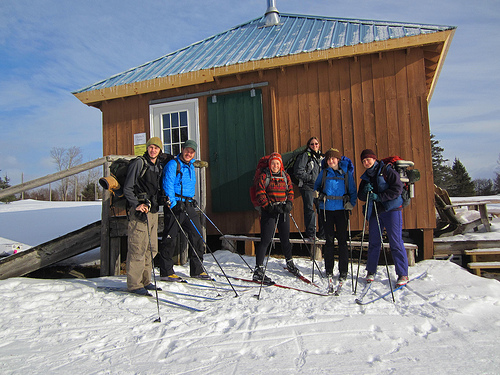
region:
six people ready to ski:
[60, 5, 477, 342]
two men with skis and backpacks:
[92, 124, 234, 311]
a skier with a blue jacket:
[158, 135, 239, 297]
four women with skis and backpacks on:
[247, 132, 442, 317]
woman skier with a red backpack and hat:
[246, 147, 310, 296]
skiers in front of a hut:
[57, 2, 499, 337]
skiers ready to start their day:
[53, 5, 480, 364]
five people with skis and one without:
[55, 24, 485, 361]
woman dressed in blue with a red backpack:
[356, 143, 435, 307]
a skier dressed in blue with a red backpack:
[352, 144, 449, 326]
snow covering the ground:
[192, 323, 390, 372]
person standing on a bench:
[288, 129, 322, 244]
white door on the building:
[138, 98, 195, 141]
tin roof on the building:
[134, 20, 355, 58]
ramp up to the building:
[5, 159, 106, 269]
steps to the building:
[453, 244, 499, 295]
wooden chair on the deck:
[433, 180, 498, 252]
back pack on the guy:
[91, 148, 133, 202]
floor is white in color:
[271, 321, 316, 371]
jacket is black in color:
[146, 159, 164, 194]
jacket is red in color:
[263, 175, 291, 208]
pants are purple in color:
[389, 215, 411, 267]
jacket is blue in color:
[321, 167, 358, 205]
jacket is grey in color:
[295, 148, 313, 178]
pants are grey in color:
[126, 213, 160, 285]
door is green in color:
[211, 108, 255, 158]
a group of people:
[109, 125, 431, 309]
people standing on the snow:
[97, 123, 424, 310]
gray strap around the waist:
[323, 189, 347, 201]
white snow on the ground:
[2, 197, 496, 374]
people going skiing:
[105, 134, 440, 316]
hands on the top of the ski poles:
[272, 199, 297, 221]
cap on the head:
[357, 146, 375, 161]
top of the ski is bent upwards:
[353, 296, 365, 309]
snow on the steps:
[462, 246, 499, 269]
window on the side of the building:
[140, 98, 206, 190]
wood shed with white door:
[79, 17, 456, 253]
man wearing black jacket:
[115, 127, 168, 302]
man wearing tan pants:
[112, 132, 168, 315]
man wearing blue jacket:
[165, 134, 220, 292]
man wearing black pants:
[167, 132, 215, 274]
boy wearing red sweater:
[241, 146, 308, 299]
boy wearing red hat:
[255, 148, 319, 287]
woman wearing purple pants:
[356, 138, 434, 300]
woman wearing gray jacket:
[292, 126, 333, 250]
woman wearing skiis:
[352, 151, 431, 338]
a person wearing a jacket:
[127, 124, 170, 216]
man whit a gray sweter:
[123, 140, 158, 276]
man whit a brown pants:
[131, 155, 150, 276]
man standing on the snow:
[176, 141, 204, 256]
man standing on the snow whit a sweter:
[261, 154, 293, 241]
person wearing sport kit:
[320, 160, 349, 252]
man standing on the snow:
[363, 163, 415, 286]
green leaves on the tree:
[451, 163, 461, 182]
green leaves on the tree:
[461, 170, 467, 185]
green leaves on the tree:
[75, 181, 110, 206]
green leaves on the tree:
[454, 161, 478, 203]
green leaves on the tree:
[455, 170, 466, 193]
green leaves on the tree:
[437, 152, 467, 193]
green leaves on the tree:
[451, 148, 488, 198]